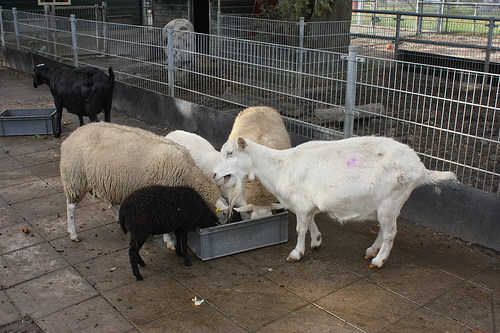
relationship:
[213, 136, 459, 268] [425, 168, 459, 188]
goat has tail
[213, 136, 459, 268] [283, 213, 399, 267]
goat has legs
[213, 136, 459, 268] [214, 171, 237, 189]
goat has mouth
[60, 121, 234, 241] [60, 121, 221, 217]
goat has fur